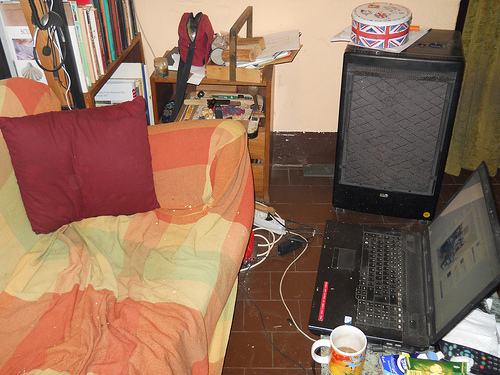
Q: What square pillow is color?
A: Red.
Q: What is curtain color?
A: Olive green.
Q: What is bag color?
A: Red.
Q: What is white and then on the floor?
A: A cord.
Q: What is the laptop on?
A: The floor.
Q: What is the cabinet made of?
A: Wood.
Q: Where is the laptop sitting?
A: On the table.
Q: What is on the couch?
A: A pillow.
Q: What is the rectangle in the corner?
A: A heater.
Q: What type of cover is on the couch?
A: A plaid blanket.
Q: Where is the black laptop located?
A: Coffee table.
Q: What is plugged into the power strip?
A: Many cords.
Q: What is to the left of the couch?
A: Wooden shelf.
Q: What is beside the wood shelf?
A: Black speaker.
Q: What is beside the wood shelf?
A: Bookcase.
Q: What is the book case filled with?
A: Books.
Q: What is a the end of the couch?
A: Pillow.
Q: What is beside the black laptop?
A: Coffee cup.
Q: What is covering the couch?
A: Plaid cloth.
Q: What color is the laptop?
A: Black.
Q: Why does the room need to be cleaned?
A: It's dirty.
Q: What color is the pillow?
A: Maroon.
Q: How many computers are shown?
A: One.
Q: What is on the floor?
A: Wires.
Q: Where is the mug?
A: Next to laptop.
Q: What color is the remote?
A: Black.